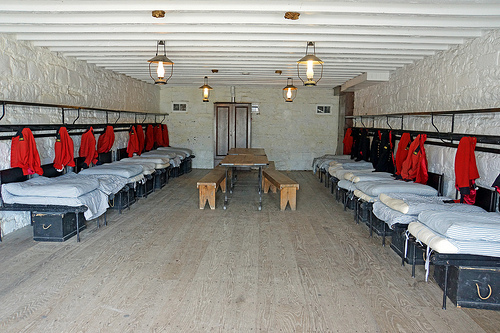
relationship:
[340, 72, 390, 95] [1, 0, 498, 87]
vent in ceiling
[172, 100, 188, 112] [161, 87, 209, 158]
air conditioning on rear wall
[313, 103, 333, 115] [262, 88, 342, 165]
air conditioning on rear wall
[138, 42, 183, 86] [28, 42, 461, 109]
lamp hanging from ceiling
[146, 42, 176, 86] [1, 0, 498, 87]
lamp hanging from ceiling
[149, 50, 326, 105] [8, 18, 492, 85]
lights in ceiling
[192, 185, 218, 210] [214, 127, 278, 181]
legs on table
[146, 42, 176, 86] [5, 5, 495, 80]
lamp hanging on ceiling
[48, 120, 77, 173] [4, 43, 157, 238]
fabric hanging on wall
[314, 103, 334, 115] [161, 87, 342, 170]
vent on rear wall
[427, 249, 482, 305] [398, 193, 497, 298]
trunks are under bed